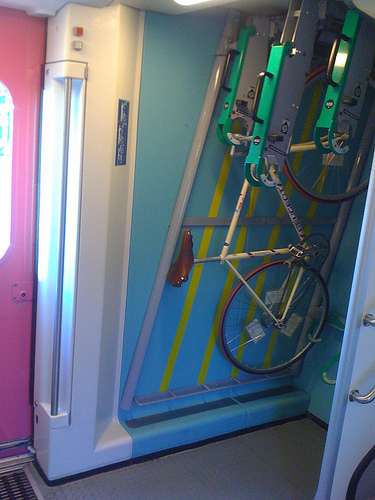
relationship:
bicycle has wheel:
[167, 63, 375, 373] [216, 257, 330, 376]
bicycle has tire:
[167, 63, 375, 373] [282, 63, 375, 205]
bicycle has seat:
[167, 63, 375, 373] [166, 222, 198, 290]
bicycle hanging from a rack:
[167, 63, 375, 373] [112, 0, 351, 403]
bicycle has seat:
[167, 63, 375, 373] [164, 225, 195, 285]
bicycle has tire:
[164, 32, 348, 363] [282, 63, 375, 205]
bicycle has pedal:
[167, 63, 375, 373] [295, 237, 327, 263]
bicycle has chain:
[167, 63, 375, 373] [264, 236, 335, 326]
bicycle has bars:
[167, 63, 375, 373] [220, 115, 289, 156]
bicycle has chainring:
[167, 63, 375, 373] [292, 225, 329, 273]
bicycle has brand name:
[167, 63, 375, 373] [269, 179, 306, 249]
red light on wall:
[65, 20, 84, 40] [25, 0, 341, 479]